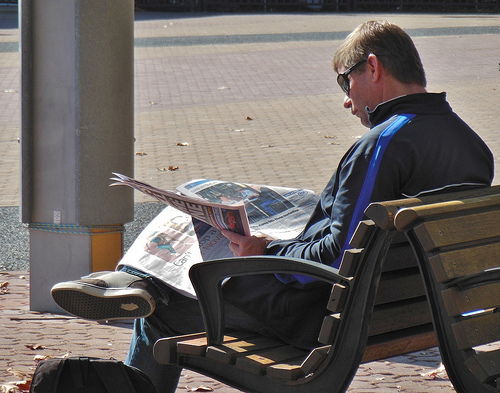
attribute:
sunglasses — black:
[337, 59, 366, 95]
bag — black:
[31, 358, 154, 392]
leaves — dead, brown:
[3, 345, 48, 392]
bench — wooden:
[154, 182, 497, 392]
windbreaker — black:
[263, 93, 494, 316]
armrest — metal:
[188, 256, 346, 348]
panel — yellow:
[90, 229, 123, 277]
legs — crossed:
[53, 211, 303, 391]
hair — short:
[334, 20, 425, 86]